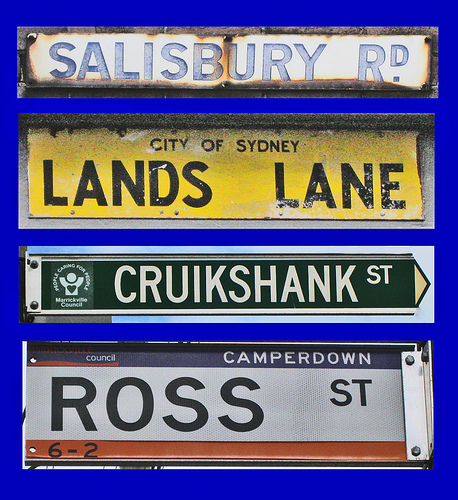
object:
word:
[43, 159, 211, 208]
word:
[222, 350, 371, 368]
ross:
[50, 374, 263, 432]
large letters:
[50, 374, 98, 431]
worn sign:
[16, 24, 437, 101]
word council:
[84, 353, 114, 363]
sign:
[22, 339, 418, 468]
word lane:
[275, 161, 406, 209]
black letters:
[274, 160, 297, 210]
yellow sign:
[28, 127, 422, 220]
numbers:
[83, 441, 100, 459]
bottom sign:
[21, 339, 436, 475]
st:
[366, 263, 395, 287]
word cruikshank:
[110, 260, 358, 304]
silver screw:
[404, 353, 414, 366]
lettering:
[41, 159, 213, 209]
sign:
[18, 108, 438, 231]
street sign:
[24, 244, 434, 325]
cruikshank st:
[114, 263, 392, 306]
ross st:
[49, 376, 372, 431]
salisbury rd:
[48, 35, 409, 86]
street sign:
[17, 25, 440, 98]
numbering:
[47, 439, 61, 459]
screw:
[410, 446, 420, 455]